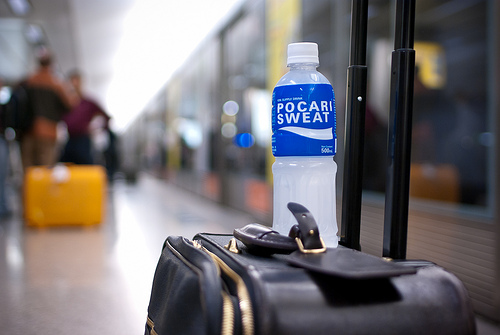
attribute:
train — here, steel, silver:
[113, 1, 499, 279]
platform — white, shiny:
[3, 153, 281, 334]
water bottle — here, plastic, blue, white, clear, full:
[273, 42, 343, 246]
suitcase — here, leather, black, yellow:
[149, 212, 476, 335]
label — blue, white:
[271, 90, 332, 146]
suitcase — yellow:
[24, 165, 101, 228]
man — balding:
[3, 56, 64, 167]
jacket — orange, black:
[15, 76, 67, 134]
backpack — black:
[4, 82, 33, 132]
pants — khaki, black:
[26, 137, 53, 168]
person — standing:
[61, 73, 105, 160]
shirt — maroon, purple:
[72, 95, 108, 135]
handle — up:
[243, 206, 323, 258]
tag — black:
[285, 243, 419, 286]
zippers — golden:
[167, 229, 254, 332]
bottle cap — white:
[286, 47, 314, 62]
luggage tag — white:
[51, 164, 71, 186]